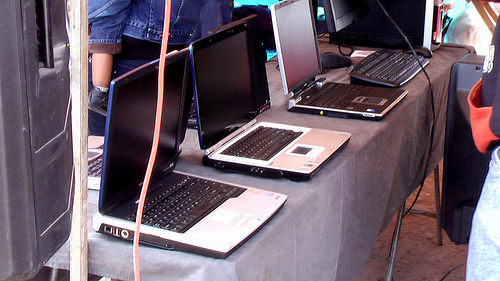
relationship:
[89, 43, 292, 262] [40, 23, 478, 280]
laptop on table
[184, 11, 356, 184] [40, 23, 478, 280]
laptop on table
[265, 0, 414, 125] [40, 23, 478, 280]
laptop on table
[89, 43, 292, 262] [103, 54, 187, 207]
laptop has screen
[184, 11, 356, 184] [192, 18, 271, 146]
laptop has screen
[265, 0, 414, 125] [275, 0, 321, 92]
laptop has screen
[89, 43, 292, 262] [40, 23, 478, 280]
laptop kept in table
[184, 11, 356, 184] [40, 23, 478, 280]
laptop kept in table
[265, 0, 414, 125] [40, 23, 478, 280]
laptop kept in table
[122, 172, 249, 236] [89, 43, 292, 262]
keyboard on laptop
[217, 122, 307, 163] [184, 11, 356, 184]
keyboard on laptop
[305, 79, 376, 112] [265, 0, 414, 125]
keyboard on laptop